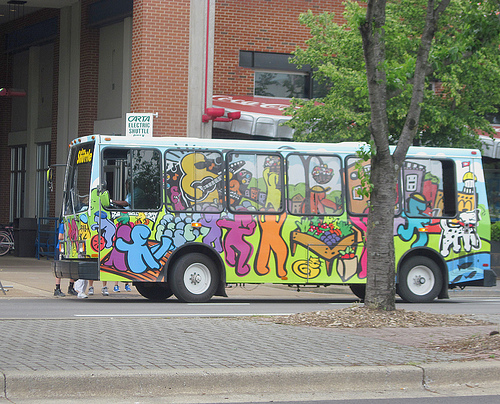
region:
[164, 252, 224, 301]
The front wheel is black.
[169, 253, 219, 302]
The front wheel is round.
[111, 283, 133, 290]
The persons shoes are blue.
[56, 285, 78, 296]
The persons shoes are black.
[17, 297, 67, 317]
The pavement is black.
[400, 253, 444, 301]
The back wheel is black.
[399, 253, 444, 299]
The back wheel is round.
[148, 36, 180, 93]
The building is made from brick.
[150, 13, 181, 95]
The building is brown.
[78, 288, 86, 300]
The persons shoe is white.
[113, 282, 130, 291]
The person's shoes are blue.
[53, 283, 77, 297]
The person's shoes are black.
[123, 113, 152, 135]
The sign is white and green.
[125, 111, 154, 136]
The writing on the sign is green.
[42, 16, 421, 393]
a bus on the road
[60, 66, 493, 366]
a bus on the street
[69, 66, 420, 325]
a passenger bus on the road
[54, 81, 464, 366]
a passenger bus on the street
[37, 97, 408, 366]
a bus that is decorated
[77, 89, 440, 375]
a decorated bus on the road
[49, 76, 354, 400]
a decorated bus on the street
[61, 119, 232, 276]
a bus with a window open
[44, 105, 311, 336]
a passenger bus with windows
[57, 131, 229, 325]
a bus with windows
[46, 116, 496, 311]
A multi-colored bus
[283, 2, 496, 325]
A tree in front of the bus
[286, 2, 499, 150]
Green leaves on the tree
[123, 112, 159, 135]
A white sign on the building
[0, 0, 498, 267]
A red brick building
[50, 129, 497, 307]
The bus is in front of the building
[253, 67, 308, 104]
Window on the building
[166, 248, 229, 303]
Front tire of the bus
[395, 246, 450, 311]
Rear tire of the bus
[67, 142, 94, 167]
Sign on front of the bus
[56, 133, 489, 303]
A medium multicolored bus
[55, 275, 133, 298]
Feet of people standing beside bus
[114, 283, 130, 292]
A pair of blue sneakers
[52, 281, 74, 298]
Pair of black shoes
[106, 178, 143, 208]
Man sitting behind the wheel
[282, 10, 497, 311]
Tree beside the bus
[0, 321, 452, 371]
Pavement made of tiles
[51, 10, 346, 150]
Building made of brick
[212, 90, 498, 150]
Red and white tent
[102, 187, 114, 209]
Green side mirror on bus